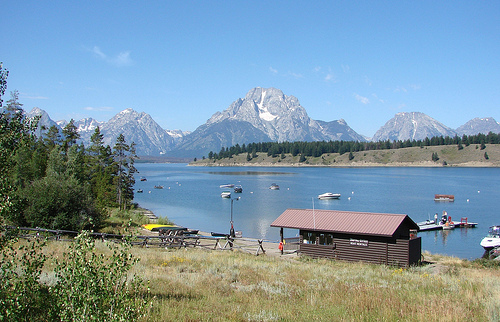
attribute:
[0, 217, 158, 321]
leaves — short, green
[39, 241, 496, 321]
grass — yellow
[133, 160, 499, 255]
water — lake, calm, blue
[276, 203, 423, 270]
store — brown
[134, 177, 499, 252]
boat — white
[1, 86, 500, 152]
mountains — majestic, gray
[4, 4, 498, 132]
sky — blue, clear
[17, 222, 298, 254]
gate — metal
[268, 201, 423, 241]
roof — brown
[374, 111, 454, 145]
shape — dome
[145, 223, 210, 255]
tables — empty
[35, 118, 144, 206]
trees — green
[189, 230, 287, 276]
grass — patchy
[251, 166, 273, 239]
water — shiny